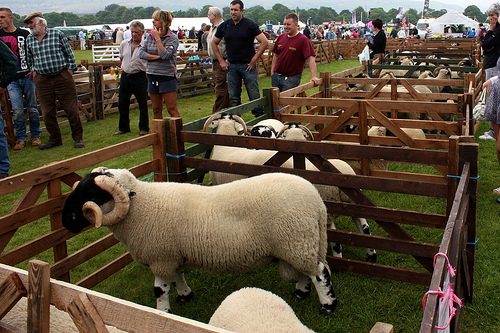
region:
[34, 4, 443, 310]
People at a fair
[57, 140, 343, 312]
This is a ram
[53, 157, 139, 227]
The rams has large horns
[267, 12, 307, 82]
Man's shirt is maroon with yellow lettering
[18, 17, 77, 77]
Man with a white beard wearing a plaid shirt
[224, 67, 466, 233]
Wood enclosures for barn animals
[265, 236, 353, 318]
This is a male sheep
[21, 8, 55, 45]
Man wearing a hat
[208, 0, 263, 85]
This man is standing with hands on hips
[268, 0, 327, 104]
This man is leaning against fence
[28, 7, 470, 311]
They appear to be judging the sheep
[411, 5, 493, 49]
There is a tent in the background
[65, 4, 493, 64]
A lot of people in attendance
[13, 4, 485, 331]
This could be a county fair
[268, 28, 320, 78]
The man is wearing a red shirt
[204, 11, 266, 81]
The man is wearing a black shirt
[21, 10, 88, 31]
The man is wearing a cap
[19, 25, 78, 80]
The man is wearing a plaid shirt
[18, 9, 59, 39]
The man has gray hair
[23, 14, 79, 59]
The man has a beard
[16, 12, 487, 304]
sheep in cages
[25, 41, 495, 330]
sheep in wooden cages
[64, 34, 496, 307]
sheep that are fenced in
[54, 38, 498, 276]
fences around the sheep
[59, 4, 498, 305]
wooden fences around sheep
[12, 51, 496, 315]
sheeps fenced in together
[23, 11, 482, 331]
sheep in different cages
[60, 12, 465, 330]
sheep in different areas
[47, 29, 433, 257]
wooden fences on a field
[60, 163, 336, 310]
a white and black ram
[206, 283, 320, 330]
a white sheep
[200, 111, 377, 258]
a white and black ram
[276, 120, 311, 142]
a white and black ram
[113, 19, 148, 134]
a man standing on grass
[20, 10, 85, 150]
a man standing on grass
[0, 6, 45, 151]
a man standing on grass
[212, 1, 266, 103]
a man standing on grass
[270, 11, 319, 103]
a man standing on grass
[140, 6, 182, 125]
a woman standing on grass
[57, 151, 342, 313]
a very pretty white goat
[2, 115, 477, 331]
a white ram in a wooden pin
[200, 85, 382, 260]
a group of three rams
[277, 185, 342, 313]
a pair of ram's hine legs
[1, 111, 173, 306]
a light wooden gate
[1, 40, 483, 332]
a bunch of ram's in pins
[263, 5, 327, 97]
a guy leaning on a wooden fence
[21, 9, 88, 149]
a man with a long sleeved checkered shirt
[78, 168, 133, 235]
a single ram horn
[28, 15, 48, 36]
white beard and white hair